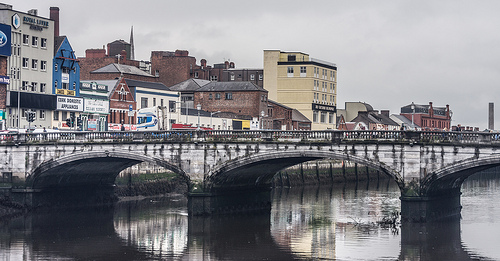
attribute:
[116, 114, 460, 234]
archway — stone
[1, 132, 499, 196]
bridge — long, stone, white, dirty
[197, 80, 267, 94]
pointed roof — black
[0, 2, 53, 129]
building — tall, white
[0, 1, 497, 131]
sky — hazy, cloud filled, overcast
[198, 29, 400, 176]
building — tall, multi story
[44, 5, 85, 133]
building — blue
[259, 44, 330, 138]
building — brown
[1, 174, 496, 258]
river — reflective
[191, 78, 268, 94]
roof — black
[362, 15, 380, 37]
sky — overcast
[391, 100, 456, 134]
house — red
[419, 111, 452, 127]
windows — many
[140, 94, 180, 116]
windows — many